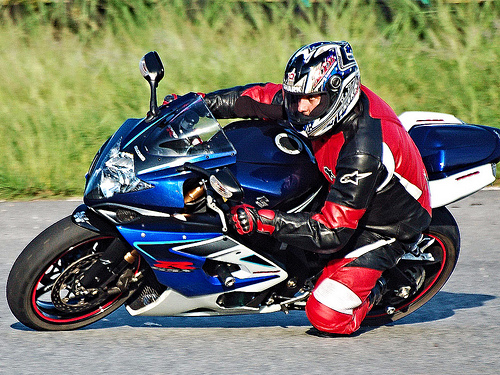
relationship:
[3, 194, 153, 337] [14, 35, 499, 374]
wheel on motorcycle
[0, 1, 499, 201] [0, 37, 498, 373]
grass on ground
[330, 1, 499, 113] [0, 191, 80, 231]
grass on ground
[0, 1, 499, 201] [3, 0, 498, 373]
grass on ground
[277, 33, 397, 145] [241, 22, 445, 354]
head of man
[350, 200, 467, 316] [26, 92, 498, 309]
wheel on motorcycle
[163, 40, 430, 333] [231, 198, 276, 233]
man wearing glove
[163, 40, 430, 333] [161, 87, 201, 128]
man wearing glove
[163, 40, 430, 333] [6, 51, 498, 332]
man leaning on motorcycle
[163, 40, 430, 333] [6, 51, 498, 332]
man in motorcycle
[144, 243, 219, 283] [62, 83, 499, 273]
logo in motorcycle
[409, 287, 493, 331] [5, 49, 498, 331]
shadow in motorbike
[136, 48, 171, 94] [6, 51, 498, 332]
mirror in motorcycle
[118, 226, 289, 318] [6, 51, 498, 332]
trim in motorcycle